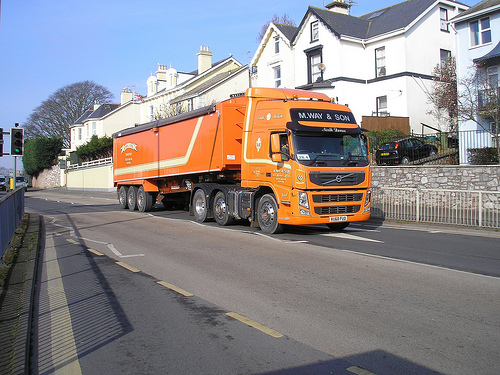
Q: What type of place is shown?
A: It is a road.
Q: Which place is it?
A: It is a road.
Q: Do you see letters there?
A: Yes, there are letters.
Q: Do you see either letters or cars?
A: Yes, there are letters.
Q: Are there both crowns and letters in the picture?
A: No, there are letters but no crowns.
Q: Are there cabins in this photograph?
A: No, there are no cabins.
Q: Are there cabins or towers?
A: No, there are no cabins or towers.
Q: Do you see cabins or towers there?
A: No, there are no cabins or towers.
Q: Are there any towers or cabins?
A: No, there are no cabins or towers.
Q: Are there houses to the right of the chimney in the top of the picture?
A: Yes, there is a house to the right of the chimney.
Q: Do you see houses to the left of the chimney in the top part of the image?
A: No, the house is to the right of the chimney.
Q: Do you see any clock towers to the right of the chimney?
A: No, there is a house to the right of the chimney.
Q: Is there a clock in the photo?
A: No, there are no clocks.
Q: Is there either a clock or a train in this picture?
A: No, there are no clocks or trains.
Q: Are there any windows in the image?
A: Yes, there is a window.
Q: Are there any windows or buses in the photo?
A: Yes, there is a window.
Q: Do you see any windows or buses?
A: Yes, there is a window.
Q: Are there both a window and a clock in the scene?
A: No, there is a window but no clocks.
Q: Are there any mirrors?
A: Yes, there is a mirror.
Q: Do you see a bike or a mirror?
A: Yes, there is a mirror.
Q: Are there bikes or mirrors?
A: Yes, there is a mirror.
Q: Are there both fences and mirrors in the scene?
A: Yes, there are both a mirror and a fence.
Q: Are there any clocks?
A: No, there are no clocks.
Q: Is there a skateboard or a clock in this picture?
A: No, there are no clocks or skateboards.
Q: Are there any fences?
A: Yes, there is a fence.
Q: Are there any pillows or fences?
A: Yes, there is a fence.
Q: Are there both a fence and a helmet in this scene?
A: No, there is a fence but no helmets.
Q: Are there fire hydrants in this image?
A: No, there are no fire hydrants.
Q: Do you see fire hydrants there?
A: No, there are no fire hydrants.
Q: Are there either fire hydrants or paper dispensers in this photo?
A: No, there are no fire hydrants or paper dispensers.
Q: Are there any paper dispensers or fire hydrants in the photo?
A: No, there are no fire hydrants or paper dispensers.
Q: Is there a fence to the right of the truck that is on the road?
A: Yes, there is a fence to the right of the truck.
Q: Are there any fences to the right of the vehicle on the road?
A: Yes, there is a fence to the right of the truck.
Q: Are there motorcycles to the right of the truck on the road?
A: No, there is a fence to the right of the truck.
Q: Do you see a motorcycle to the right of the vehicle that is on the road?
A: No, there is a fence to the right of the truck.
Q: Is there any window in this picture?
A: Yes, there is a window.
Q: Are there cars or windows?
A: Yes, there is a window.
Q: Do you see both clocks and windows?
A: No, there is a window but no clocks.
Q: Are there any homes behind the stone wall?
A: Yes, there are homes behind the wall.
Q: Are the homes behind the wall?
A: Yes, the homes are behind the wall.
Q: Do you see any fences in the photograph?
A: Yes, there is a fence.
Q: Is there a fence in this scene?
A: Yes, there is a fence.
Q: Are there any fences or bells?
A: Yes, there is a fence.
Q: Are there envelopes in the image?
A: No, there are no envelopes.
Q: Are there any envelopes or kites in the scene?
A: No, there are no envelopes or kites.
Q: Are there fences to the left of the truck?
A: Yes, there is a fence to the left of the truck.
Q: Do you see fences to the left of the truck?
A: Yes, there is a fence to the left of the truck.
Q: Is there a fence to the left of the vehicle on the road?
A: Yes, there is a fence to the left of the truck.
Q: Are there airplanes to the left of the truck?
A: No, there is a fence to the left of the truck.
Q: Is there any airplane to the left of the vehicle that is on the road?
A: No, there is a fence to the left of the truck.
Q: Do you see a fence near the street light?
A: Yes, there is a fence near the street light.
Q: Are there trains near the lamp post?
A: No, there is a fence near the lamp post.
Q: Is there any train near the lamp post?
A: No, there is a fence near the lamp post.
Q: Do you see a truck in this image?
A: Yes, there is a truck.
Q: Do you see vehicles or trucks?
A: Yes, there is a truck.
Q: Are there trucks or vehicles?
A: Yes, there is a truck.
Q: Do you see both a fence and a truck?
A: Yes, there are both a truck and a fence.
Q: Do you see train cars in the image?
A: No, there are no train cars.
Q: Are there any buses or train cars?
A: No, there are no train cars or buses.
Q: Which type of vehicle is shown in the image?
A: The vehicle is a truck.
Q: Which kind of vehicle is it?
A: The vehicle is a truck.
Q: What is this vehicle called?
A: This is a truck.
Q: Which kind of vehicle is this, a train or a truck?
A: This is a truck.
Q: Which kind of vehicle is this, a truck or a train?
A: This is a truck.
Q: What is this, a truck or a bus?
A: This is a truck.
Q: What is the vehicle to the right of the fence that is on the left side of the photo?
A: The vehicle is a truck.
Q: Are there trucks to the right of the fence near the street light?
A: Yes, there is a truck to the right of the fence.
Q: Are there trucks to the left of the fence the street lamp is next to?
A: No, the truck is to the right of the fence.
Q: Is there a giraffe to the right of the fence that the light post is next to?
A: No, there is a truck to the right of the fence.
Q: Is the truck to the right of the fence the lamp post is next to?
A: Yes, the truck is to the right of the fence.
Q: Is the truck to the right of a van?
A: No, the truck is to the right of the fence.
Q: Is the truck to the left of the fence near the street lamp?
A: No, the truck is to the right of the fence.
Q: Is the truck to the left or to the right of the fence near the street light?
A: The truck is to the right of the fence.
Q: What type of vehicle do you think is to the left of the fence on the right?
A: The vehicle is a truck.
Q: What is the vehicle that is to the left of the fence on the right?
A: The vehicle is a truck.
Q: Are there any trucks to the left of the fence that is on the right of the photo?
A: Yes, there is a truck to the left of the fence.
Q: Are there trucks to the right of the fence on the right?
A: No, the truck is to the left of the fence.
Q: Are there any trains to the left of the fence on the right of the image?
A: No, there is a truck to the left of the fence.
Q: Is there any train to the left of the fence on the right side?
A: No, there is a truck to the left of the fence.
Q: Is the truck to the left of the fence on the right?
A: Yes, the truck is to the left of the fence.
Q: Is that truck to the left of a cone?
A: No, the truck is to the left of the fence.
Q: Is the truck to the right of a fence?
A: No, the truck is to the left of a fence.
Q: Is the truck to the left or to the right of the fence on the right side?
A: The truck is to the left of the fence.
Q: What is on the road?
A: The truck is on the road.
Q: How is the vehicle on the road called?
A: The vehicle is a truck.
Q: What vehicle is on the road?
A: The vehicle is a truck.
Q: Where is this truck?
A: The truck is on the road.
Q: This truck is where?
A: The truck is on the road.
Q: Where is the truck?
A: The truck is on the road.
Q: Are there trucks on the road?
A: Yes, there is a truck on the road.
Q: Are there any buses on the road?
A: No, there is a truck on the road.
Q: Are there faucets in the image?
A: No, there are no faucets.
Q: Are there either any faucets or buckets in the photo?
A: No, there are no faucets or buckets.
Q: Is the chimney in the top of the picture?
A: Yes, the chimney is in the top of the image.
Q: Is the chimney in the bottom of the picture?
A: No, the chimney is in the top of the image.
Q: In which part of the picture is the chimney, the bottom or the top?
A: The chimney is in the top of the image.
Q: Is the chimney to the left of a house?
A: Yes, the chimney is to the left of a house.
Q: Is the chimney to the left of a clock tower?
A: No, the chimney is to the left of a house.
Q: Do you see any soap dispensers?
A: No, there are no soap dispensers.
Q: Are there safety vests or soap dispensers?
A: No, there are no soap dispensers or safety vests.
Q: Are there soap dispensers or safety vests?
A: No, there are no soap dispensers or safety vests.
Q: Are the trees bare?
A: Yes, the trees are bare.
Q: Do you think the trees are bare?
A: Yes, the trees are bare.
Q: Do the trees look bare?
A: Yes, the trees are bare.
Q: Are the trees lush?
A: No, the trees are bare.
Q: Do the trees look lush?
A: No, the trees are bare.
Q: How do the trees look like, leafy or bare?
A: The trees are bare.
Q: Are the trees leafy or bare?
A: The trees are bare.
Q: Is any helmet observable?
A: No, there are no helmets.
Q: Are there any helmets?
A: No, there are no helmets.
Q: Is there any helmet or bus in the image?
A: No, there are no helmets or buses.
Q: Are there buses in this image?
A: No, there are no buses.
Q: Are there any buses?
A: No, there are no buses.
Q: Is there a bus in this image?
A: No, there are no buses.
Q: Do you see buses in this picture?
A: No, there are no buses.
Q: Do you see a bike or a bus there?
A: No, there are no buses or bikes.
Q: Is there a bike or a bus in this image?
A: No, there are no buses or bikes.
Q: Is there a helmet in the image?
A: No, there are no helmets.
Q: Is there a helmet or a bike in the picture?
A: No, there are no helmets or bikes.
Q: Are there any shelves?
A: No, there are no shelves.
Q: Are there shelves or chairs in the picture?
A: No, there are no shelves or chairs.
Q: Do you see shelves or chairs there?
A: No, there are no shelves or chairs.